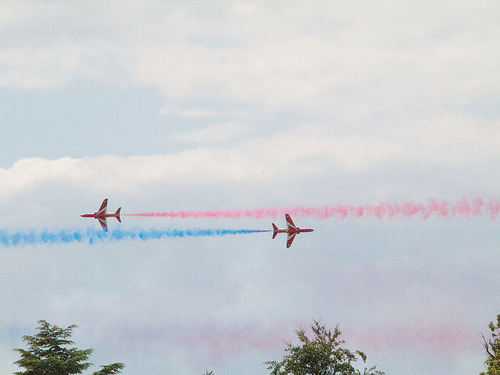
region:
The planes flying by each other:
[31, 142, 481, 322]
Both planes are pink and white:
[46, 152, 367, 286]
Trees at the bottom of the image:
[16, 246, 470, 373]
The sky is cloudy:
[27, 21, 472, 251]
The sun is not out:
[3, 8, 457, 195]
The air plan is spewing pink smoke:
[76, 170, 477, 221]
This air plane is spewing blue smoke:
[4, 210, 285, 261]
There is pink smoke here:
[68, 259, 472, 361]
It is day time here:
[30, 18, 464, 363]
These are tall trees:
[23, 287, 495, 365]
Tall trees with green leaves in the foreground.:
[8, 312, 496, 373]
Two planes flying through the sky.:
[28, 70, 487, 295]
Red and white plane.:
[263, 207, 320, 247]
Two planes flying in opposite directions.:
[65, 185, 332, 260]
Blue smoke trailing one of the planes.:
[5, 221, 270, 253]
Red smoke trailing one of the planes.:
[129, 194, 457, 222]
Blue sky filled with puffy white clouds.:
[25, 42, 395, 179]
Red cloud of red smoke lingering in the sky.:
[155, 312, 475, 357]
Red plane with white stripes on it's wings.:
[264, 210, 316, 252]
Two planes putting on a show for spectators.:
[27, 115, 472, 354]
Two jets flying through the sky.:
[72, 166, 403, 272]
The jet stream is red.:
[130, 190, 496, 232]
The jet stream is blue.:
[1, 207, 271, 262]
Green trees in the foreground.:
[1, 297, 496, 372]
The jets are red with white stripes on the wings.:
[65, 175, 338, 266]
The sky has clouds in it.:
[16, 20, 497, 181]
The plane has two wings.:
[280, 205, 301, 257]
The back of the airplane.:
[110, 196, 126, 226]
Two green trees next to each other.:
[10, 295, 435, 373]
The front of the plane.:
[300, 222, 317, 241]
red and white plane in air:
[78, 192, 123, 233]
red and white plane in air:
[271, 208, 312, 258]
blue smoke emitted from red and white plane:
[17, 232, 254, 240]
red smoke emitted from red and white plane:
[138, 207, 275, 218]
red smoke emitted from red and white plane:
[311, 205, 481, 218]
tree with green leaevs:
[25, 315, 97, 370]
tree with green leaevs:
[274, 315, 354, 370]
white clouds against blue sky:
[12, 5, 188, 148]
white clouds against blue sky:
[166, 12, 468, 187]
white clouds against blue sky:
[26, 256, 473, 312]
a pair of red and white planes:
[55, 166, 326, 273]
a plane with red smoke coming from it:
[57, 182, 134, 225]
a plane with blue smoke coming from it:
[253, 202, 338, 255]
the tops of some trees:
[13, 303, 493, 373]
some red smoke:
[98, 309, 498, 369]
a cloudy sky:
[8, 7, 498, 373]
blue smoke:
[1, 223, 273, 243]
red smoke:
[125, 196, 496, 221]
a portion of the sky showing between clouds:
[9, 95, 264, 152]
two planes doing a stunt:
[36, 148, 390, 325]